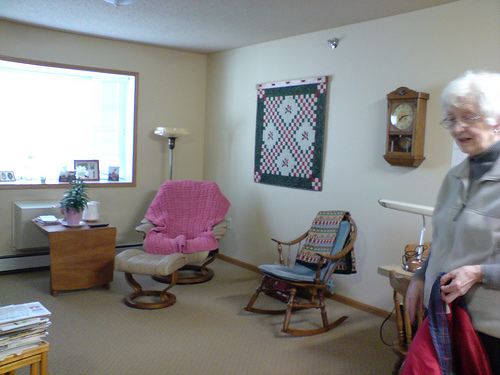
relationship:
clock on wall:
[390, 101, 417, 130] [371, 50, 397, 88]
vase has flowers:
[64, 205, 84, 225] [62, 165, 88, 199]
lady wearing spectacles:
[427, 59, 500, 340] [440, 113, 479, 129]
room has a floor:
[9, 7, 492, 370] [80, 318, 263, 358]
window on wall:
[1, 55, 145, 188] [371, 50, 397, 88]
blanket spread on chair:
[141, 181, 230, 255] [243, 203, 366, 339]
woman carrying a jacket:
[427, 59, 500, 340] [393, 268, 493, 374]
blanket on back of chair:
[167, 192, 207, 228] [243, 203, 366, 339]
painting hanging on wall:
[250, 75, 331, 190] [371, 50, 397, 88]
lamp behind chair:
[146, 118, 191, 180] [243, 208, 358, 337]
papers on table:
[2, 298, 57, 356] [46, 226, 115, 265]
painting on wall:
[258, 83, 325, 150] [371, 50, 397, 88]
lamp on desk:
[372, 193, 441, 222] [378, 251, 414, 282]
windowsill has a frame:
[15, 177, 63, 185] [133, 73, 137, 186]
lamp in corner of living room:
[146, 118, 191, 180] [9, 7, 492, 370]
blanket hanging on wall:
[167, 192, 207, 228] [371, 50, 397, 88]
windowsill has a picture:
[15, 177, 63, 185] [71, 156, 103, 184]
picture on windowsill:
[71, 156, 103, 184] [15, 177, 63, 185]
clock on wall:
[382, 85, 428, 169] [371, 50, 397, 88]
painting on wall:
[250, 75, 331, 190] [371, 50, 397, 88]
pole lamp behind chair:
[146, 118, 191, 180] [243, 203, 366, 339]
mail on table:
[36, 209, 63, 230] [46, 226, 115, 265]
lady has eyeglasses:
[403, 70, 499, 375] [440, 113, 479, 129]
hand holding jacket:
[438, 266, 473, 308] [393, 268, 493, 374]